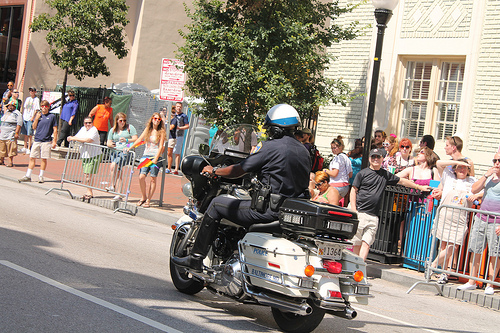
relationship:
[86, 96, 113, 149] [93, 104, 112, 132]
man wearing shirt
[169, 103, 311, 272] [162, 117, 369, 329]
cop on motorcycle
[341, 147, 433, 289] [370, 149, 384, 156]
man wearing cap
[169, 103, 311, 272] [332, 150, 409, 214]
cop wearing shirt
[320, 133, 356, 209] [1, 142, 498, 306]
girl looking at sidewalk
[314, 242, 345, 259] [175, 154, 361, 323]
plate on bike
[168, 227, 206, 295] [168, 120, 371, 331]
tire on bike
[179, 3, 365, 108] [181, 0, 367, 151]
leaves on tree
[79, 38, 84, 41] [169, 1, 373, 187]
leaves on tree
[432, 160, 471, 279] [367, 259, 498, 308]
lady on sidewalk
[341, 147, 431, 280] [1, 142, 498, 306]
man on sidewalk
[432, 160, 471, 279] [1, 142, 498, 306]
lady on sidewalk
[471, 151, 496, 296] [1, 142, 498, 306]
person on sidewalk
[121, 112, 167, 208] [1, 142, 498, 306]
girl on sidewalk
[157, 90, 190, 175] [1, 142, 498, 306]
person on sidewalk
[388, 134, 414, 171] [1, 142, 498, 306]
person on sidewalk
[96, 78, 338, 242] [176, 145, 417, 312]
cop riding motorcycle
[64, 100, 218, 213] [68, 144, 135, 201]
people leaning on gate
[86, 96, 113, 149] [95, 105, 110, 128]
man wearing shirt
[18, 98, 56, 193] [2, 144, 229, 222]
standing man on sidewalk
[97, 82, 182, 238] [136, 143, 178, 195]
girl holding flag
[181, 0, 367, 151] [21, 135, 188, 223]
tree on sidewalk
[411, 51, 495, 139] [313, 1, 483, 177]
windows in building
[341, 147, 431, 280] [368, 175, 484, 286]
man against rail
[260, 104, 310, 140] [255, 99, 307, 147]
helmet on head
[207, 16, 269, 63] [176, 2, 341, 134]
leaves on tree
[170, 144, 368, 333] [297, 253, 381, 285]
bike has lights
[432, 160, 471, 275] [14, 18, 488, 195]
lady blocking sun